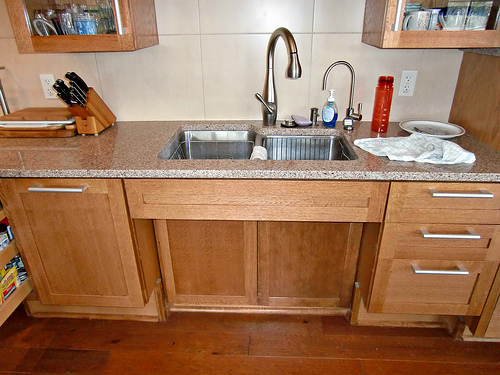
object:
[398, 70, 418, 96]
outlet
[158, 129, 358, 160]
sink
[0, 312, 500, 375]
floor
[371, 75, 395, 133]
water bottle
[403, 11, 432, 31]
mug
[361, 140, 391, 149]
ground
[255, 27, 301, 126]
faucet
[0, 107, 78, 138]
boards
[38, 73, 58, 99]
outlet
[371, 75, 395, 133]
bottle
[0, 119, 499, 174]
counter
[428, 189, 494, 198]
handle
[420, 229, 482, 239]
handle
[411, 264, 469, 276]
handle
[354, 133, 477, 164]
rag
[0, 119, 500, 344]
cabinet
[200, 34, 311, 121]
tile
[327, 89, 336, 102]
hand pump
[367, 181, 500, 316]
drawer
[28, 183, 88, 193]
handle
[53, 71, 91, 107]
kitchen knives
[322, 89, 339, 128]
bottle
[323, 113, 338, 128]
hand soap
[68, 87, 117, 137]
block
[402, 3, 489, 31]
cups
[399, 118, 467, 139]
plate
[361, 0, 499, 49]
cabinet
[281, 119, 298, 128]
sink stopper